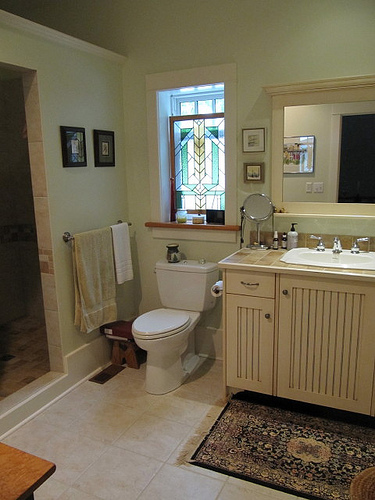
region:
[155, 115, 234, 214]
a stained glass window insert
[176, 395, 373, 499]
an area rug on a floor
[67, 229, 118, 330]
a towel on a towel rack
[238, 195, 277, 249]
a make up mirror on a counter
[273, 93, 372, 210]
a mirror on a wall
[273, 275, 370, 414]
a door of a cabinet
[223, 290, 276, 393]
a door of a cabinet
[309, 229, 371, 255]
the faucet of a bathroom sink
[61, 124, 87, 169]
a picture in a frame on a wall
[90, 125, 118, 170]
a picture in a frame on a wall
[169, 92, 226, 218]
A bathroom window with stained glass.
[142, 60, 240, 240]
White window frame with a wooden window sill.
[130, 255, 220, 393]
A white bathroom toilet.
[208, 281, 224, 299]
Roll of toilet paper on a toilet paper holder.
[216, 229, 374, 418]
Tan cabinet with a tiled top.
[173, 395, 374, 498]
A throw rug with white fringes on the end.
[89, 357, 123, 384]
A vent on the floor next to the toilet.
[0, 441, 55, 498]
Edge of a brown wooden stand.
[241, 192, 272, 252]
Round silver mirror on a silver base.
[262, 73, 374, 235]
Bathroom window in a white frame.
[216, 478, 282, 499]
tan tile on floor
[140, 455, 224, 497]
tan tile on floor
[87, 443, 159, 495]
tan tile on floor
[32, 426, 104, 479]
tan tile on floor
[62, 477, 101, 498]
tan tile on floor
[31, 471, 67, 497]
tan tile on floor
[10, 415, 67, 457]
tan tile on floor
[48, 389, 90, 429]
tan tile on floor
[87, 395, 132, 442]
tan tile on floor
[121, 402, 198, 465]
tan tile on floor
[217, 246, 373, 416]
Cabinet in the bathroom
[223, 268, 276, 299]
Drawer on the cabinet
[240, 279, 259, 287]
Handle on the drawer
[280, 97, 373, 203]
Mirror on the wall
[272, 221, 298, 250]
Toiletries on the counter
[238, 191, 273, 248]
Mirror on the counter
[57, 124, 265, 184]
Pictures on the wall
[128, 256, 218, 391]
Toilet in the bathroom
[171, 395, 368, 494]
Rug on the floor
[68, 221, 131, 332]
Towels on the rack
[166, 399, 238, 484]
a rug on the floor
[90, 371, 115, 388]
a vent on the floor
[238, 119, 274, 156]
a picture on the wall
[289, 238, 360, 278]
a sink on the counter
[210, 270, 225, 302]
toilet paper on the roll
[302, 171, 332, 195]
an outlet on the wall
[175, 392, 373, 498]
black and gold throw rug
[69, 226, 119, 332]
yellow towel on a towel rack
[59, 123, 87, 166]
framed art on the wall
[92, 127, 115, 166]
framed art on the wall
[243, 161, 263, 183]
framed art on the wall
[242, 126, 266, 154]
framed art on the wall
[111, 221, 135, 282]
white hand towel on a towel rack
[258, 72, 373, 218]
mirror with an off white frame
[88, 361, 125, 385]
vent on the floor